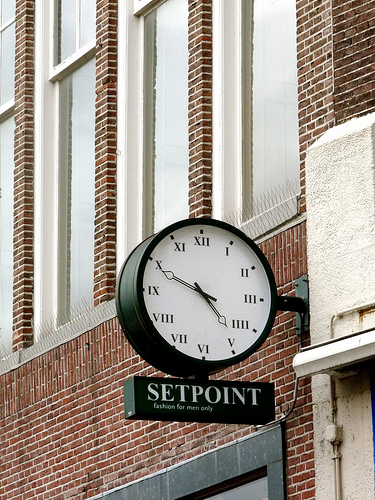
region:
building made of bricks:
[30, 413, 120, 451]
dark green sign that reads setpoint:
[127, 375, 277, 431]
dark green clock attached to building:
[112, 217, 289, 372]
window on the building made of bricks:
[64, 186, 94, 298]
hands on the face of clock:
[168, 263, 230, 327]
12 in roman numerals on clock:
[193, 233, 214, 248]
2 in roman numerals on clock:
[233, 262, 253, 282]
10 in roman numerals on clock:
[155, 260, 164, 270]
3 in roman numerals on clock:
[240, 291, 260, 301]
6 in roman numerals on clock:
[195, 342, 212, 354]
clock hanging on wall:
[92, 200, 284, 383]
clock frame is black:
[105, 208, 286, 377]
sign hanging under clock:
[115, 363, 281, 432]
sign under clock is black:
[114, 365, 283, 429]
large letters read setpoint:
[140, 377, 262, 408]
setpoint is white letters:
[142, 378, 262, 407]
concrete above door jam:
[293, 101, 374, 350]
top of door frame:
[63, 419, 289, 497]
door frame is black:
[65, 418, 286, 498]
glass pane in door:
[191, 466, 270, 499]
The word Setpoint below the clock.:
[143, 378, 265, 404]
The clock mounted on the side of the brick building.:
[123, 216, 284, 377]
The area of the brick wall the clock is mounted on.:
[251, 227, 318, 455]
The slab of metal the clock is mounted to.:
[289, 274, 314, 332]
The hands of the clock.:
[161, 258, 226, 330]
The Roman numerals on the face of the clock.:
[147, 225, 258, 356]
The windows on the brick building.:
[0, 3, 266, 349]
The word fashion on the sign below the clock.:
[149, 401, 176, 411]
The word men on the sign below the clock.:
[184, 403, 199, 411]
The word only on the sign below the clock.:
[200, 402, 215, 412]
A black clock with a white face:
[116, 216, 281, 373]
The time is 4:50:
[154, 267, 244, 330]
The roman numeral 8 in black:
[151, 307, 176, 327]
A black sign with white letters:
[121, 375, 275, 424]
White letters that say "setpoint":
[145, 381, 264, 406]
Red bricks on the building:
[36, 395, 107, 472]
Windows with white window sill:
[34, 4, 96, 111]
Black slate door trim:
[160, 452, 289, 490]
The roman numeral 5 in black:
[225, 334, 237, 351]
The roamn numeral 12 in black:
[192, 229, 212, 252]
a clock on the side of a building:
[114, 216, 275, 364]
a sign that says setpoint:
[117, 368, 303, 433]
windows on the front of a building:
[31, 149, 316, 354]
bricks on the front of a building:
[16, 331, 134, 490]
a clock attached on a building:
[117, 219, 291, 370]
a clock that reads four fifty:
[131, 210, 290, 361]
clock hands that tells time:
[161, 258, 241, 334]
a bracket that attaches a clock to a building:
[244, 257, 320, 352]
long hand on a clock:
[162, 266, 211, 296]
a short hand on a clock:
[195, 282, 232, 328]